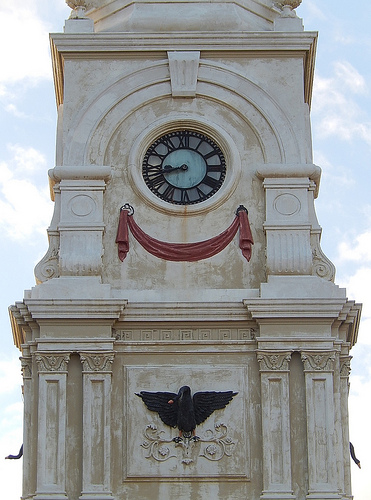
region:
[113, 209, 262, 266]
a stone painted banner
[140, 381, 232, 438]
a stone black swan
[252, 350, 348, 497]
decorative pillars on a tower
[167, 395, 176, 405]
the orange beak of a swan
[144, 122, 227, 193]
the face of a clock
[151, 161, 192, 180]
the hour and minute hands on a clock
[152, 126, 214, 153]
roman numerals on a clockface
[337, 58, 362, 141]
white clouds in the sky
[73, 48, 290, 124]
decorative arch in a clock tower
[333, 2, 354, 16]
a patch of blue sky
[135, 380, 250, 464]
An eagle is on the tower.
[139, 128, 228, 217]
The clock has roman numbers.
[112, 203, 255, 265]
The ribbon underneath the clock is red.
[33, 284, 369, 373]
The tower is beige.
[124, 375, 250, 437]
The eagle is black.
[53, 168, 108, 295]
The clock has columns.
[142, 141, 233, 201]
The face of the clock is brown.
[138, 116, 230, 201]
The clock is round.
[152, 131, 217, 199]
The time on the clock is 8:45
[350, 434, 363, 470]
A black item hanging from the tower.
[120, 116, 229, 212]
Black and white clock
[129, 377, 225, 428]
Statue of a black bird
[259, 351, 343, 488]
Columns on each side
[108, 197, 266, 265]
Long red draped curtain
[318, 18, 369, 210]
Blue sky with clouds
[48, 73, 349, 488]
Tall, white and beige monument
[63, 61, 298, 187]
Arch over the clock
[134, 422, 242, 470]
Decorative spiraling leaves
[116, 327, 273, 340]
A row of decorative, small, spiraling boxes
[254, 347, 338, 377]
Intricate design on top of each column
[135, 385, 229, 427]
this is a statue of a bird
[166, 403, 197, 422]
the birds is black in color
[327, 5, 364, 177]
this is the sky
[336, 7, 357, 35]
the sky is blue in color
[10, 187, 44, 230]
these are the clouds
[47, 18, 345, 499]
this is a building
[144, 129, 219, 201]
this is a clock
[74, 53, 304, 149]
this is the wall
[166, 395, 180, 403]
the bird has a long beak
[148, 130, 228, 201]
the clock is round in shape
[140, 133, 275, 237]
Large clock on tower.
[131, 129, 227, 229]
Numbers on clock are roman numerals.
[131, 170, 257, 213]
Hands on the clock are black.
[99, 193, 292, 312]
Red object underneath of clock.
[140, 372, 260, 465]
Black bird statue on tower.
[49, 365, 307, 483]
Tower is grayish brown in color.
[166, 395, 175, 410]
Bird statue has orange beak.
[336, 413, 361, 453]
Bird statue on right side of tower.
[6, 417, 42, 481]
Bird statue on left of statue.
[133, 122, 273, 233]
Face on clock is gray in color.